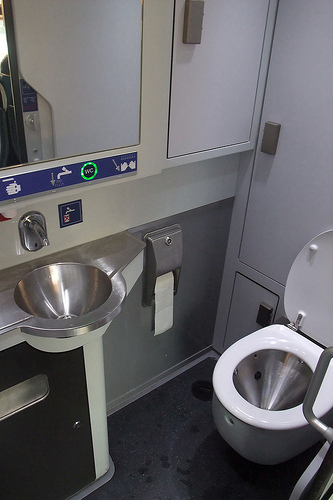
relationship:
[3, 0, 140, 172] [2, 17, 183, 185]
mirror reflecting a wall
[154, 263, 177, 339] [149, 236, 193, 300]
toilet paper in dispenser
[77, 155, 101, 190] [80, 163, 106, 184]
light around button